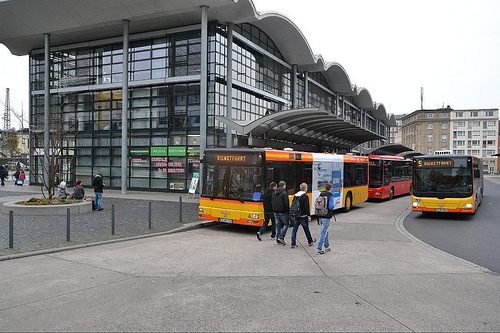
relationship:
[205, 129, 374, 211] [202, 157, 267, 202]
bus has windshield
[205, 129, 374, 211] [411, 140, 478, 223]
bus next to bus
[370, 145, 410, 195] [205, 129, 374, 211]
bus behind bus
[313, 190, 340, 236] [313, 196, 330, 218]
person carrying backpack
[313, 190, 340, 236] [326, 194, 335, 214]
person with hoodie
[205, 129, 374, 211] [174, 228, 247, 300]
bus on road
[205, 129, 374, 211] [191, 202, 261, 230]
bus has headlights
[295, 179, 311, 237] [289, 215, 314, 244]
man wearing jeans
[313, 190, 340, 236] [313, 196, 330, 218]
person wearing backpack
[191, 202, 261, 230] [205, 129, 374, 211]
headlights on bus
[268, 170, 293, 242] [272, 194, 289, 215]
person wearing coat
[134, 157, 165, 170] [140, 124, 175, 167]
sign on windo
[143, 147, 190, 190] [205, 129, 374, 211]
advertisement on bus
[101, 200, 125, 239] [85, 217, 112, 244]
post on ground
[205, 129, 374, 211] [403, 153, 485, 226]
bus next to bus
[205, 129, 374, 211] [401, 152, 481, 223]
bus next to bus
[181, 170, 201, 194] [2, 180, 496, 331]
sign on a street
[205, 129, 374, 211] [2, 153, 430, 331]
bus at a bus stop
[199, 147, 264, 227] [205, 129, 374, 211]
front of a bus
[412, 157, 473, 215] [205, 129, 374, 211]
front of a bus